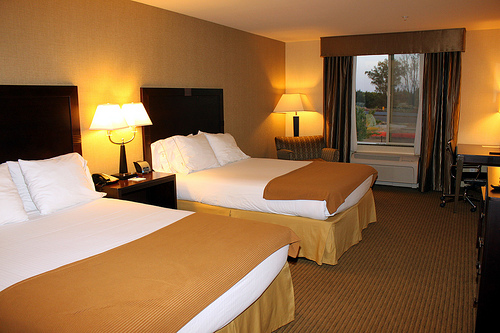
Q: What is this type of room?
A: Hotel room.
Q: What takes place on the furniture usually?
A: Sleep.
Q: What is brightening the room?
A: Lamps.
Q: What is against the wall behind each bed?
A: Headboard.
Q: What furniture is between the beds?
A: Nightstand.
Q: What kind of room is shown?
A: A hotel room.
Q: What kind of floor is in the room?
A: Carpeted floor.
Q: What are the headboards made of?
A: Wood.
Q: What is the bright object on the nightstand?
A: A lamp.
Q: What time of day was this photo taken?
A: Dusk.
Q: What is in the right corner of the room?
A: A desk.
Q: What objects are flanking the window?
A: Curtains.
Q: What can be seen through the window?
A: A tree.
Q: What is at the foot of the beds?
A: Blankets.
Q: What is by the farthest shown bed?
A: A chair.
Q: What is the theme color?
A: Brown.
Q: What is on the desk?
A: Lamp.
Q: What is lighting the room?
A: Lamp.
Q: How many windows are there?
A: 1.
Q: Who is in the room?
A: No one.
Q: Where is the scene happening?
A: In a hotel room.